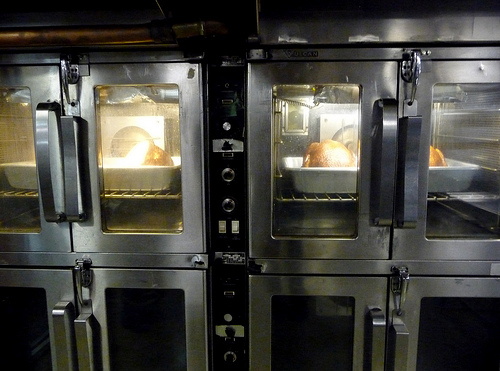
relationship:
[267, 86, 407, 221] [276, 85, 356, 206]
light inside window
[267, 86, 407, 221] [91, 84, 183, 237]
light inside window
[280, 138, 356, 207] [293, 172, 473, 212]
food sitting on rack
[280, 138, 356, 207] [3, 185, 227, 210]
food sitting on rack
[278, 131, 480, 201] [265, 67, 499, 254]
food cooking behind window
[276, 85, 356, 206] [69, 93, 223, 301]
window on door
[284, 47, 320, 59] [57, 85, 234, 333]
sticker on door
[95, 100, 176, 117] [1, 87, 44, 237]
light on window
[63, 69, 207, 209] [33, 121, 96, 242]
light on handle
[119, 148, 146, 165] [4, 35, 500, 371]
light in ovens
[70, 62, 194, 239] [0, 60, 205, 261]
window on oven door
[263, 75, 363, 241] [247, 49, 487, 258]
window on oven door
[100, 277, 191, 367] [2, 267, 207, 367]
window on oven door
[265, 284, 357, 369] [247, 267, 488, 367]
window on oven door